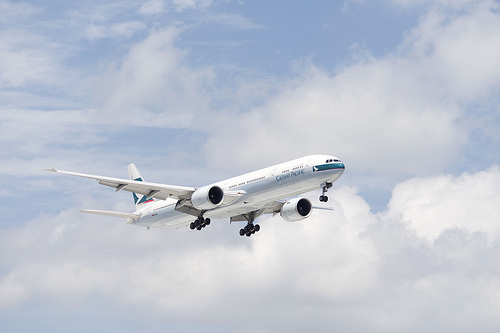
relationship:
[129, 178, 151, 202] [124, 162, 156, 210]
blue design on blue/plane tail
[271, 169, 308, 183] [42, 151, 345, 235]
writing on plane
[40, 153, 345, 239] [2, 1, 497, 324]
airplane flying in a sky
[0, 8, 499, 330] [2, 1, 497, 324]
clouds are on sky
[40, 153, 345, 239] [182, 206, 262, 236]
airplane has tires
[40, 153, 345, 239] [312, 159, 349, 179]
airplane has front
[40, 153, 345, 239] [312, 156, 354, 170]
airplane has windows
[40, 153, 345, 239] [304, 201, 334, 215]
airplane has wing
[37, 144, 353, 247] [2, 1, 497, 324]
airplane in sky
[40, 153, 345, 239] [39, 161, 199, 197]
airplane has wing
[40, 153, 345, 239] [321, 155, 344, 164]
airplane has windows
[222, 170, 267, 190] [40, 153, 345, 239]
windows on airplane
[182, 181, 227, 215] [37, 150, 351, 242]
engine on plane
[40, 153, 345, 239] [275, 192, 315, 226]
airplane has engine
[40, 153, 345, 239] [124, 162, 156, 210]
airplane has blue/plane tail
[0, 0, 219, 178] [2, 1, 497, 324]
clouds in sky